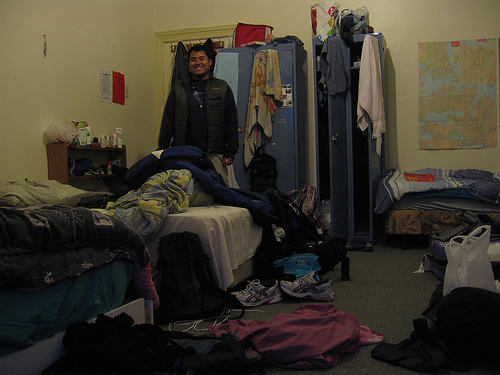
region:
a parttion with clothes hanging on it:
[227, 25, 439, 269]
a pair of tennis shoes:
[222, 270, 364, 316]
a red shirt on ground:
[202, 324, 423, 359]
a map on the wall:
[417, 21, 489, 153]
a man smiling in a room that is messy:
[157, 46, 244, 193]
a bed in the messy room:
[4, 163, 147, 345]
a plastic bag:
[426, 226, 496, 277]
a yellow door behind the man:
[134, 10, 276, 101]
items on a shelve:
[42, 110, 124, 164]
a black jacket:
[175, 83, 259, 165]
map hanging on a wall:
[415, 38, 497, 148]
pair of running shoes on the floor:
[231, 273, 333, 298]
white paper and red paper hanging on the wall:
[96, 66, 129, 106]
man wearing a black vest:
[161, 43, 236, 164]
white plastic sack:
[441, 225, 496, 293]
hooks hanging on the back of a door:
[161, 38, 230, 50]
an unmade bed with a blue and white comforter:
[384, 164, 496, 223]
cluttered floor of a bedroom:
[22, 228, 485, 365]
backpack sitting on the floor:
[157, 232, 224, 318]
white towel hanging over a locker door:
[353, 33, 393, 155]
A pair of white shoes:
[226, 263, 359, 308]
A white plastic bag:
[430, 216, 495, 297]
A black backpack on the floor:
[147, 225, 239, 320]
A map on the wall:
[410, 26, 495, 161]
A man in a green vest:
[146, 37, 241, 177]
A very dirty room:
[0, 2, 495, 369]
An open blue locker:
[310, 17, 390, 242]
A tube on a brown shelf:
[110, 121, 125, 147]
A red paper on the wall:
[107, 62, 123, 102]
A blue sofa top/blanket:
[0, 252, 135, 357]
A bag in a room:
[442, 223, 492, 294]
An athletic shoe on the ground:
[230, 280, 279, 304]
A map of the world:
[415, 38, 498, 150]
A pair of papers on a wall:
[97, 70, 129, 103]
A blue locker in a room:
[312, 32, 383, 249]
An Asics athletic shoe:
[280, 270, 333, 300]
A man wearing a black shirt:
[159, 45, 236, 162]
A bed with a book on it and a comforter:
[378, 168, 498, 243]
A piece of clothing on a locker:
[244, 48, 279, 170]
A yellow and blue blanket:
[103, 169, 215, 237]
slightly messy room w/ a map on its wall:
[0, 2, 499, 374]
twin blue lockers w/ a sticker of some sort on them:
[204, 34, 306, 248]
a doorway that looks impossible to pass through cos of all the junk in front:
[147, 20, 244, 177]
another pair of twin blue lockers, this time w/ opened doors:
[306, 25, 388, 265]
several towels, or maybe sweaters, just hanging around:
[236, 33, 393, 170]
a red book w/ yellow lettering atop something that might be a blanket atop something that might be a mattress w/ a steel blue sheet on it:
[398, 167, 438, 187]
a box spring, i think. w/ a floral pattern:
[371, 208, 497, 240]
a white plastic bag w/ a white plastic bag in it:
[436, 217, 498, 312]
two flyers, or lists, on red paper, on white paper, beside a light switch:
[91, 60, 133, 105]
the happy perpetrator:
[156, 39, 238, 189]